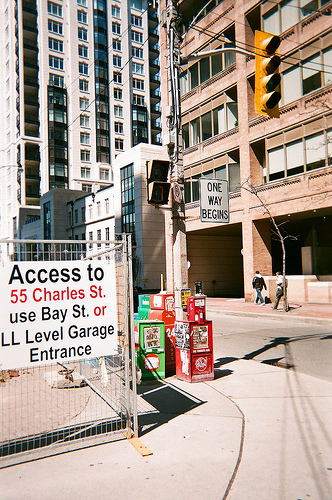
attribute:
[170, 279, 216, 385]
machine — red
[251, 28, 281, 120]
stop light — yellow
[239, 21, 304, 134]
street light — tall, yellow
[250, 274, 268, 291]
jacket — black, leather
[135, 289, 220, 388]
machines — newspaper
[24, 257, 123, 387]
sign — large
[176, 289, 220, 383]
dispenser — tall, red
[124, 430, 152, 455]
plank — wooden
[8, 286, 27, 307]
number — orange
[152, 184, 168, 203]
number — orange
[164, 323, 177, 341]
number — orange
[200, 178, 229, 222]
sign — white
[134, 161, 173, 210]
light — pedestrian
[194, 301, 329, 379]
street — empty, city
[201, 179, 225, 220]
sign — white and black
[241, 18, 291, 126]
light — yellow, traffic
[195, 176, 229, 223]
traffic sign — black and white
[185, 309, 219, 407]
box — metal and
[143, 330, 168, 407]
box — green and metal